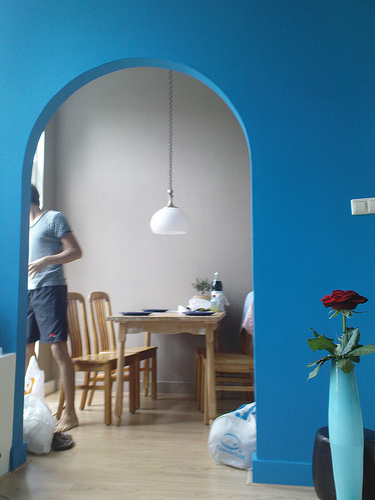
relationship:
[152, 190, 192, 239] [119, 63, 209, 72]
light hanging from ceiling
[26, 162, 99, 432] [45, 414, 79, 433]
man has bare feet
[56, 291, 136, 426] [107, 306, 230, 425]
chair on table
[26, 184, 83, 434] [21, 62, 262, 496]
man on dining room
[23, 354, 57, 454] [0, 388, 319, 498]
bag on floor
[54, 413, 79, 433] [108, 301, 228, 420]
bare feet standing next to table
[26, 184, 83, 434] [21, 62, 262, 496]
man standing on dining room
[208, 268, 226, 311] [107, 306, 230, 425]
bottle on top of table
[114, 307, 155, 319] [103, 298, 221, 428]
plate on table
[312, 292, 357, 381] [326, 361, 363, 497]
rose in vase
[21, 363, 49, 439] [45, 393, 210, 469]
bag on floor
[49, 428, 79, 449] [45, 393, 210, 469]
shoe on floor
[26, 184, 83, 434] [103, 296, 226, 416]
man gets up table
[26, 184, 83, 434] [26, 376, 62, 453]
man takes out garbage